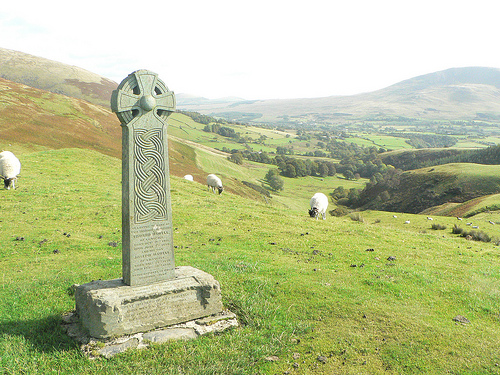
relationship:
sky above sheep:
[3, 0, 499, 97] [4, 147, 338, 234]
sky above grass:
[3, 0, 499, 97] [9, 100, 500, 370]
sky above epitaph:
[3, 0, 499, 97] [70, 71, 218, 338]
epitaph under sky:
[70, 71, 218, 338] [3, 0, 499, 97]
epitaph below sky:
[70, 71, 218, 338] [3, 0, 499, 97]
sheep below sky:
[4, 147, 338, 234] [3, 0, 499, 97]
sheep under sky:
[4, 147, 338, 234] [3, 0, 499, 97]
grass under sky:
[9, 100, 500, 370] [3, 0, 499, 97]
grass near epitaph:
[9, 100, 500, 370] [70, 71, 218, 338]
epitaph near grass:
[70, 71, 218, 338] [9, 100, 500, 370]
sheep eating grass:
[4, 147, 338, 234] [359, 255, 384, 265]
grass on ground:
[0, 146, 500, 375] [237, 217, 498, 362]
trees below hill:
[270, 153, 395, 176] [270, 191, 295, 212]